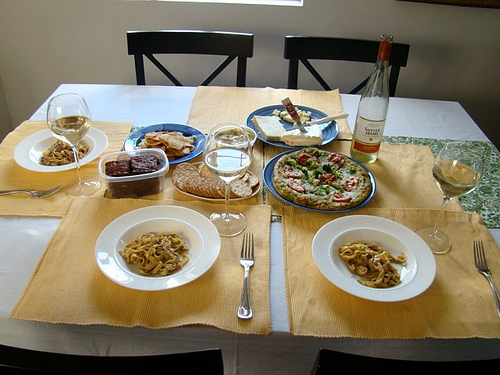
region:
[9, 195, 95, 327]
an orange table place mat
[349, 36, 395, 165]
a bottle of wine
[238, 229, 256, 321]
a dinner fork on the table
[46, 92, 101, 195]
a wine goblet on the table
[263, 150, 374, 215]
a pizza on a serving dish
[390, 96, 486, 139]
a white table cloth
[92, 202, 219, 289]
a white ceramic bowl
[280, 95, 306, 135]
a brown handle cheese knife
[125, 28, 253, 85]
brown wooden dining room chairs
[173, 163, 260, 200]
crackers on a plate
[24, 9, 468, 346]
table set for three people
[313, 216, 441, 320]
noodles in a white bowl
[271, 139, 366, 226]
a vege pizza on a blue plate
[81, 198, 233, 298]
noodles with sauch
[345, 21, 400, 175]
white wine for everyone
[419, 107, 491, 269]
half full glass of wine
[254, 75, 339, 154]
bread and butter on blue plate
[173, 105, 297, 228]
crackers and cheese behind a glass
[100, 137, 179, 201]
bread in a plastic dish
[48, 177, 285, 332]
yellow placemat under dishes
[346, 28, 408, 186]
Bottle of wine on table.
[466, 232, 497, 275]
Silver fork sitting on table.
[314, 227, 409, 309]
White bowl sitting on table.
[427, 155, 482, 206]
White wine in wine glass.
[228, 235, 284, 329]
Silver fork sitting on table.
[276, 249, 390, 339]
Gold place mat sitting on table.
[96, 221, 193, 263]
Round white bowl sitting on place mat.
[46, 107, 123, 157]
White wine in wine glass.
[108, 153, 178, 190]
Brown food in container.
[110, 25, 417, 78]
2 chairs pushed up to table.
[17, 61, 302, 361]
bowls on a table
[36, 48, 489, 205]
bowls of noodles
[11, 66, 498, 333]
white bowls on a table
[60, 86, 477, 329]
a table with white bowls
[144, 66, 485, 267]
a table with blue plates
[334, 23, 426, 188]
a bottle of wine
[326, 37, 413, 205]
a bottle of wine on the table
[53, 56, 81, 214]
wine glasses on a table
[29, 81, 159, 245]
a table with wine glass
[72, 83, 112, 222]
wine glasses with wine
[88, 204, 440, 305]
two round white bowls of pasta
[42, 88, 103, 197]
one partially full wine glass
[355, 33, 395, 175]
one partially full wine bottle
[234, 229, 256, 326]
one shiny metal fork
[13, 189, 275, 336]
bowl of food on yellow placemat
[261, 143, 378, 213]
small round pizza on blue plate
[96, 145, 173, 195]
rectangular plastic container of brownies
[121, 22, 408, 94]
two dark chair backs at table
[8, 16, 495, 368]
kitchen table set for several people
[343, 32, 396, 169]
one wine bottle with red and white label